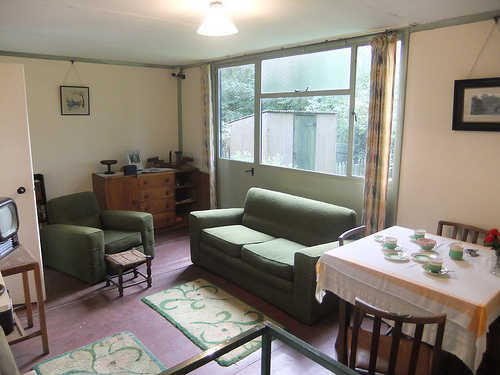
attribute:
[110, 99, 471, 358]
room — corner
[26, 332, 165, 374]
rug — small, yellow, green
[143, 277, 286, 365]
rug — white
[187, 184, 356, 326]
sofa — green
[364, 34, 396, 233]
drape — pink, gray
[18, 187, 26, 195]
knob — black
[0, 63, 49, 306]
door — pink, open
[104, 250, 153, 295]
stool — small, foot, wooden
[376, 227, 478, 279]
cups and saucers — pink, green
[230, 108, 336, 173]
shed — behind the house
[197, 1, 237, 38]
light fixture — large, on, white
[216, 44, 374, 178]
window — pictured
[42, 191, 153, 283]
chair — green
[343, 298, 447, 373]
chair — wooden, for dining room, brown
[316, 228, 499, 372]
table cloth — white, gold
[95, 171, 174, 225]
dresser — brown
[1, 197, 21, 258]
part of tv — small